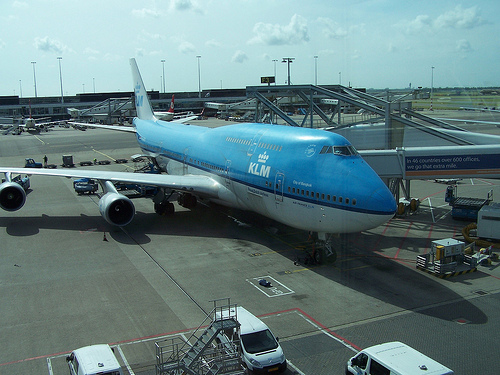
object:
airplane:
[113, 89, 476, 233]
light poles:
[185, 49, 222, 110]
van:
[212, 306, 283, 370]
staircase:
[155, 300, 228, 372]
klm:
[231, 160, 278, 179]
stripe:
[135, 140, 400, 217]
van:
[345, 336, 457, 373]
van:
[205, 307, 285, 374]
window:
[353, 198, 358, 206]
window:
[345, 197, 351, 202]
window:
[339, 195, 345, 201]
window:
[323, 192, 329, 202]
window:
[305, 188, 310, 195]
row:
[286, 185, 356, 207]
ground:
[420, 141, 472, 184]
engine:
[0, 173, 27, 210]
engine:
[97, 180, 135, 227]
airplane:
[0, 62, 404, 284]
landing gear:
[303, 227, 339, 272]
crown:
[256, 150, 269, 164]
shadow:
[232, 214, 487, 329]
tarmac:
[3, 132, 493, 373]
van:
[63, 342, 128, 373]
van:
[208, 299, 288, 371]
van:
[339, 335, 461, 373]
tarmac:
[0, 136, 496, 348]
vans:
[193, 293, 449, 372]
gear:
[150, 182, 223, 222]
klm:
[247, 160, 270, 178]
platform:
[153, 299, 260, 374]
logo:
[233, 152, 298, 193]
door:
[273, 168, 285, 204]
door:
[246, 130, 261, 157]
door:
[180, 148, 190, 171]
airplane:
[119, 55, 398, 256]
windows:
[320, 142, 361, 157]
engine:
[80, 182, 161, 245]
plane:
[5, 55, 497, 254]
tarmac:
[1, 109, 498, 374]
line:
[280, 252, 370, 274]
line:
[344, 259, 395, 272]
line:
[257, 245, 296, 255]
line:
[275, 232, 305, 252]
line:
[292, 237, 317, 246]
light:
[194, 56, 204, 85]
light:
[312, 54, 318, 82]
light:
[57, 55, 64, 93]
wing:
[1, 160, 225, 201]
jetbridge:
[351, 141, 485, 183]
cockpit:
[318, 141, 362, 160]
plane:
[1, 57, 406, 266]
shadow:
[1, 195, 499, 324]